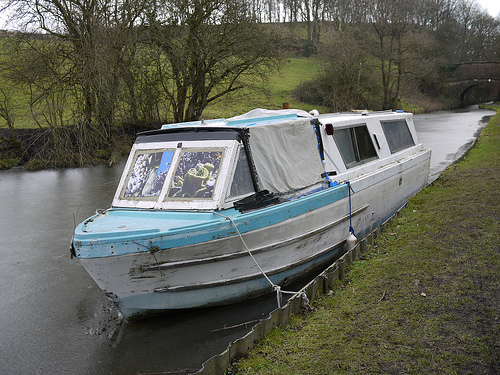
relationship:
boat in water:
[57, 91, 445, 321] [2, 86, 488, 372]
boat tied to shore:
[57, 91, 445, 321] [283, 146, 500, 370]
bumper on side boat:
[334, 227, 363, 258] [57, 91, 445, 321]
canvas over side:
[238, 115, 336, 195] [57, 91, 445, 321]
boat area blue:
[57, 91, 445, 321] [65, 181, 351, 262]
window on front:
[104, 136, 240, 213] [65, 122, 254, 317]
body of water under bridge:
[430, 96, 496, 150] [433, 59, 499, 89]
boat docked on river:
[57, 91, 445, 321] [0, 167, 76, 373]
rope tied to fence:
[210, 207, 309, 308] [180, 241, 382, 372]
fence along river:
[180, 241, 382, 372] [2, 86, 488, 372]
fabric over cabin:
[152, 100, 335, 201] [113, 104, 325, 205]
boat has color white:
[57, 91, 445, 321] [346, 103, 440, 214]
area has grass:
[283, 146, 500, 370] [345, 174, 500, 370]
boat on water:
[57, 91, 445, 321] [2, 86, 488, 372]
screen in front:
[104, 136, 240, 213] [65, 122, 254, 317]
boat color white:
[57, 91, 445, 321] [346, 103, 440, 214]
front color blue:
[65, 122, 254, 317] [65, 181, 351, 262]